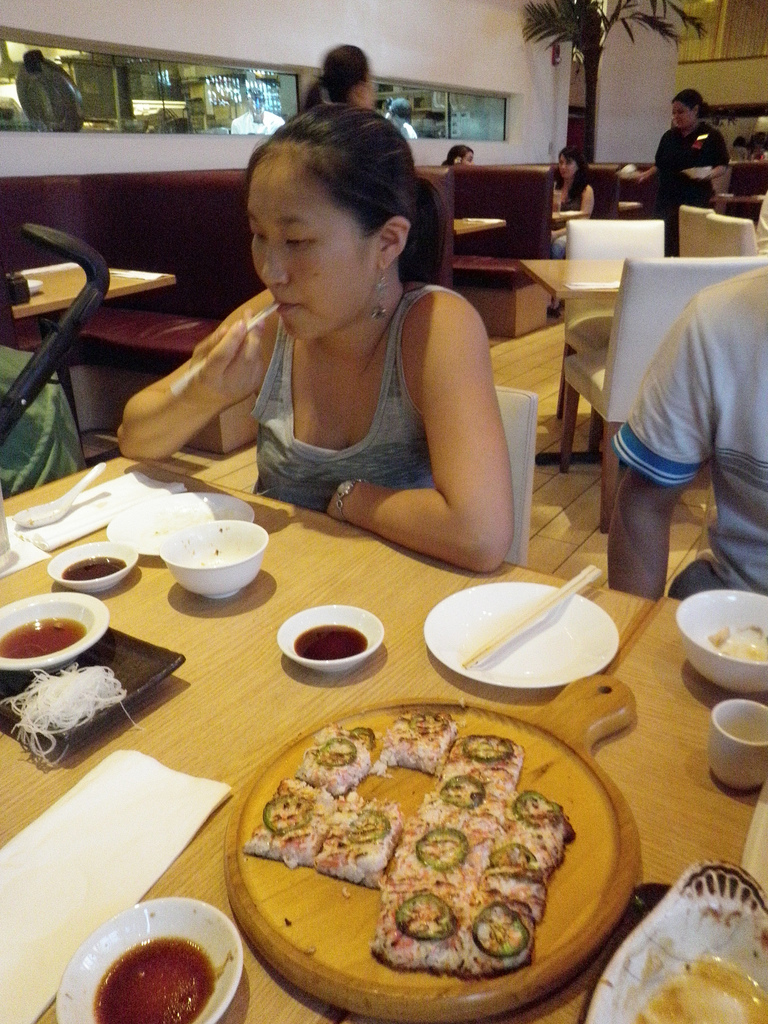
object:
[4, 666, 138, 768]
noodle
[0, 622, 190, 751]
tray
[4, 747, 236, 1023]
napkin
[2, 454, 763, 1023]
table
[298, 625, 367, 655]
sauce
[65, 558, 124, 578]
sauce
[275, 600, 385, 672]
bowl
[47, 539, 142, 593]
bowl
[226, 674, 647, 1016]
board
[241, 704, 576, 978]
food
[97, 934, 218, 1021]
red sauce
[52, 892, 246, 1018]
bowl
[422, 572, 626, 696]
plate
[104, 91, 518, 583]
woman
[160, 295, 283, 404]
chopsticks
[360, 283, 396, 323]
earring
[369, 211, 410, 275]
ear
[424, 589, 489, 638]
white plate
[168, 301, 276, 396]
pair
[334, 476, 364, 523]
watch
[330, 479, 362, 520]
wrist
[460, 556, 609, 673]
chopstick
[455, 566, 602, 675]
set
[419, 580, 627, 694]
plate